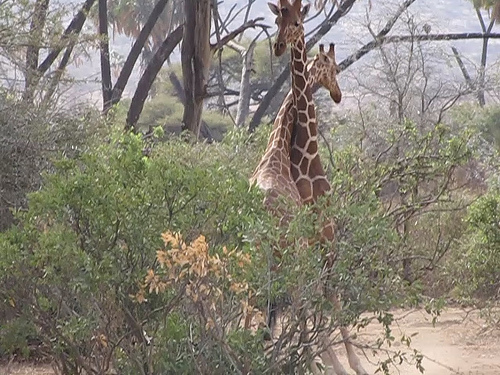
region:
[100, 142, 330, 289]
a big green bush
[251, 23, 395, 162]
two big giraffes hugging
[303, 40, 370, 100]
a brown spotted giraffe head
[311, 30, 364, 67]
brown spotted giraffe ears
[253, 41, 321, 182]
brown spotted giraffe neck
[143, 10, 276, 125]
a big tree without leaves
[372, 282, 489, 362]
a patch of brown dirt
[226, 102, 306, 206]
brown spotted giraffe back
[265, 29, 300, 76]
brown spotted giraffe nose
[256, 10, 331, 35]
big black giraffe eyes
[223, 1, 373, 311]
Two giraffes standing close together.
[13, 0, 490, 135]
Trees in the background.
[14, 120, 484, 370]
Green bushes in the foreground.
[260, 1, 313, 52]
Horns on giraffe facing camera.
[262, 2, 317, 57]
Head of giraffe facing camera.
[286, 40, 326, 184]
Neck of giraffe facing camera.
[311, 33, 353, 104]
Horns on head of giraffe looking away.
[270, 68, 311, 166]
Neck of giraffe looking away.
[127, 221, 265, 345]
A bush with brown leaves.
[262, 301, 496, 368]
Ground is very sandy.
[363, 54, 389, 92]
white clouds in blue sky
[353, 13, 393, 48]
white clouds in blue sky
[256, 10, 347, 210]
spotted giraffe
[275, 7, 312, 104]
spotted giraffe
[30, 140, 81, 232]
green leaves on brown branches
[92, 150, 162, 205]
green leaves on brown branches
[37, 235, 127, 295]
green leaves on brown branches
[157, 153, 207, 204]
green leaves on brown branches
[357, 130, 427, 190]
green leaves on brown branches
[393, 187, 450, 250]
green leaves on brown branches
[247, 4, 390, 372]
two griaffes standing on the dirt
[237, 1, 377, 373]
giraffe leaning on another giraffe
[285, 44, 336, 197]
brown spots along the neck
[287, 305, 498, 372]
dirt on the ground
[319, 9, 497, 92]
tree that is leaning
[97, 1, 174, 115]
tree that forks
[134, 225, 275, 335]
yellow leaves on the branches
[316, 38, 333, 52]
two small horns at the top of the head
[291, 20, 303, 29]
small black eye on the side of the head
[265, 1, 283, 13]
ear sticking out of the side of the head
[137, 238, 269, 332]
the dead brown leaves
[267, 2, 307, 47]
the giraffe head facing this way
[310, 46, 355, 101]
the giraffe head facing the other way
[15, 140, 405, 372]
the bush in the front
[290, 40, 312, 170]
the front giraffe's neck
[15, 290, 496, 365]
the dirt ground they are on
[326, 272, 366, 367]
the front giraffe legs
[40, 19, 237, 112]
the bare trees on left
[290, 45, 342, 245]
the spots on the front giraffe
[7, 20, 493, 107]
the sky in the background